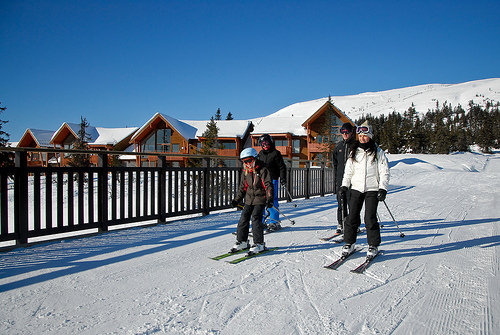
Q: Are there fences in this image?
A: Yes, there is a fence.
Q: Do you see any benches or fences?
A: Yes, there is a fence.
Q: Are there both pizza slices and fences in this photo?
A: No, there is a fence but no pizza slices.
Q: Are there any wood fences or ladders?
A: Yes, there is a wood fence.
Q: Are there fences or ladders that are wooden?
A: Yes, the fence is wooden.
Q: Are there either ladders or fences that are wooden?
A: Yes, the fence is wooden.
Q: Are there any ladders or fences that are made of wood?
A: Yes, the fence is made of wood.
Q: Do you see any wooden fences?
A: Yes, there is a wood fence.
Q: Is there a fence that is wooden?
A: Yes, there is a fence that is wooden.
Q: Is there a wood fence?
A: Yes, there is a fence that is made of wood.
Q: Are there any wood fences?
A: Yes, there is a fence that is made of wood.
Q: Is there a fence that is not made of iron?
A: Yes, there is a fence that is made of wood.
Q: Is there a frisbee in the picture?
A: No, there are no frisbees.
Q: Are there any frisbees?
A: No, there are no frisbees.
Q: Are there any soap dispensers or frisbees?
A: No, there are no frisbees or soap dispensers.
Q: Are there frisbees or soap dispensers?
A: No, there are no frisbees or soap dispensers.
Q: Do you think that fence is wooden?
A: Yes, the fence is wooden.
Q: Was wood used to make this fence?
A: Yes, the fence is made of wood.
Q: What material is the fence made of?
A: The fence is made of wood.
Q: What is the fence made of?
A: The fence is made of wood.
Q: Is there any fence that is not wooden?
A: No, there is a fence but it is wooden.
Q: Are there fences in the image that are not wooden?
A: No, there is a fence but it is wooden.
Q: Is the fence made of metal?
A: No, the fence is made of wood.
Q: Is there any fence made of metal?
A: No, there is a fence but it is made of wood.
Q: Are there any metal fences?
A: No, there is a fence but it is made of wood.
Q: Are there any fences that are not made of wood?
A: No, there is a fence but it is made of wood.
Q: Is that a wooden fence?
A: Yes, that is a wooden fence.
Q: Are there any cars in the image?
A: No, there are no cars.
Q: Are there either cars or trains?
A: No, there are no cars or trains.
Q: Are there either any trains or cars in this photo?
A: No, there are no cars or trains.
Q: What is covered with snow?
A: The roof is covered with snow.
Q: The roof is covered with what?
A: The roof is covered with snow.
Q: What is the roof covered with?
A: The roof is covered with snow.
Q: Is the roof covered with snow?
A: Yes, the roof is covered with snow.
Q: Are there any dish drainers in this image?
A: No, there are no dish drainers.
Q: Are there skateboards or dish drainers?
A: No, there are no dish drainers or skateboards.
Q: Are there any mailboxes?
A: No, there are no mailboxes.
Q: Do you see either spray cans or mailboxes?
A: No, there are no mailboxes or spray cans.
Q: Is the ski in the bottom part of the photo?
A: Yes, the ski is in the bottom of the image.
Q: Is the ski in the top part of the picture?
A: No, the ski is in the bottom of the image.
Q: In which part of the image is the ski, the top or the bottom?
A: The ski is in the bottom of the image.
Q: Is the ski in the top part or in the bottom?
A: The ski is in the bottom of the image.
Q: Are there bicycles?
A: No, there are no bicycles.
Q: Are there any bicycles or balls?
A: No, there are no bicycles or balls.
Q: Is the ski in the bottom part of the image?
A: Yes, the ski is in the bottom of the image.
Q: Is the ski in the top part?
A: No, the ski is in the bottom of the image.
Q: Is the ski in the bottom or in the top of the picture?
A: The ski is in the bottom of the image.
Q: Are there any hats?
A: Yes, there is a hat.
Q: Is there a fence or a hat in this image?
A: Yes, there is a hat.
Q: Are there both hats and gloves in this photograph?
A: Yes, there are both a hat and gloves.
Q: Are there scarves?
A: No, there are no scarves.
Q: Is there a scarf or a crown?
A: No, there are no scarves or crowns.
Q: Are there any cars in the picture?
A: No, there are no cars.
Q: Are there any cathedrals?
A: No, there are no cathedrals.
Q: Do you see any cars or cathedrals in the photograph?
A: No, there are no cathedrals or cars.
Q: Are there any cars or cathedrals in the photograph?
A: No, there are no cathedrals or cars.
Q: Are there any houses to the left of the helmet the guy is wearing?
A: Yes, there is a house to the left of the helmet.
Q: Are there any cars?
A: No, there are no cars.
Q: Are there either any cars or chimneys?
A: No, there are no cars or chimneys.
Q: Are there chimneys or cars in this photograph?
A: No, there are no cars or chimneys.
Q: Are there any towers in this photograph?
A: No, there are no towers.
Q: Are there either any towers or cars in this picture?
A: No, there are no towers or cars.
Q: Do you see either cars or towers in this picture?
A: No, there are no towers or cars.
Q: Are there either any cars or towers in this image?
A: No, there are no towers or cars.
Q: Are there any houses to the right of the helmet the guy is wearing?
A: Yes, there is a house to the right of the helmet.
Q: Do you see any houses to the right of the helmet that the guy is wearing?
A: Yes, there is a house to the right of the helmet.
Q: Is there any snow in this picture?
A: Yes, there is snow.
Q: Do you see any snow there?
A: Yes, there is snow.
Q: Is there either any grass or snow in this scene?
A: Yes, there is snow.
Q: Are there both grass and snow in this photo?
A: No, there is snow but no grass.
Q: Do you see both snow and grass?
A: No, there is snow but no grass.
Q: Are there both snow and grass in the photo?
A: No, there is snow but no grass.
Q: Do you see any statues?
A: No, there are no statues.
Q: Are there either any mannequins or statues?
A: No, there are no statues or mannequins.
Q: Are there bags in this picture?
A: No, there are no bags.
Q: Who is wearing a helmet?
A: The guy is wearing a helmet.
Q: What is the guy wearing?
A: The guy is wearing a helmet.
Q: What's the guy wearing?
A: The guy is wearing a helmet.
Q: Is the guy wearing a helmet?
A: Yes, the guy is wearing a helmet.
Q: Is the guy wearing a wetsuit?
A: No, the guy is wearing a helmet.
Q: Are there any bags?
A: No, there are no bags.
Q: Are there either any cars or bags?
A: No, there are no bags or cars.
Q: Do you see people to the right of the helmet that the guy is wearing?
A: Yes, there is a person to the right of the helmet.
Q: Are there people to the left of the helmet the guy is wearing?
A: No, the person is to the right of the helmet.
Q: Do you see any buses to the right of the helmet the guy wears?
A: No, there is a person to the right of the helmet.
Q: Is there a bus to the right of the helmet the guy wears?
A: No, there is a person to the right of the helmet.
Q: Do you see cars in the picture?
A: No, there are no cars.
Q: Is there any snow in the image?
A: Yes, there is snow.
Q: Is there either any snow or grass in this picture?
A: Yes, there is snow.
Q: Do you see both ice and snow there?
A: No, there is snow but no ice.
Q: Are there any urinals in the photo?
A: No, there are no urinals.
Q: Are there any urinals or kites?
A: No, there are no urinals or kites.